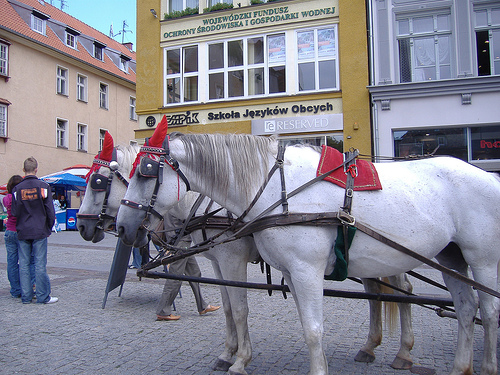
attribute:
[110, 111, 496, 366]
horse — white, beautiful, large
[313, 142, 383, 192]
blanket — red, maroon, gold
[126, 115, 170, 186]
tassel — red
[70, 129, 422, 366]
horse — large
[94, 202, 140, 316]
sign — advertisement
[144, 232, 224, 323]
man — walking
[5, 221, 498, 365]
sidewalk — cobblestone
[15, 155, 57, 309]
man — standing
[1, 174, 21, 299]
woman — standing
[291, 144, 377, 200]
reins — brown, black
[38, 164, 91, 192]
umbrella — pepsi-cola, blue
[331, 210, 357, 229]
buckle — silver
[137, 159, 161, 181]
eye covering — black, blinder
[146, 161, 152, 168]
button — silver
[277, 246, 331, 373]
leg — white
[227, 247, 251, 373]
leg — white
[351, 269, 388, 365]
leg — white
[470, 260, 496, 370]
leg — white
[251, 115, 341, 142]
sign — silver, grey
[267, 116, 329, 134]
letters — white, "reserved"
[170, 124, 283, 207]
mane — grayish brown, little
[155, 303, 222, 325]
shoes — brown, dress shoes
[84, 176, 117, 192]
blinder — black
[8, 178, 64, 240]
jacket — blue, white, orange, navy blue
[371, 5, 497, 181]
brick — gray, old, worn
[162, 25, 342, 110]
frame — white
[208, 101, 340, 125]
store name — black